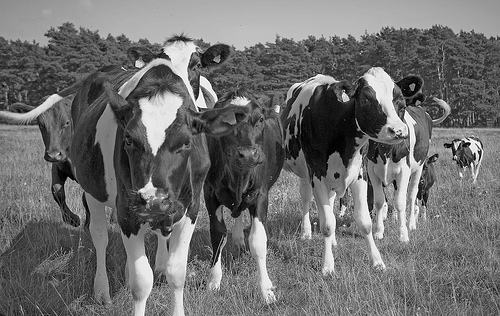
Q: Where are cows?
A: On grass.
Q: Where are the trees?
A: Behind cows.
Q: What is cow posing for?
A: Photo.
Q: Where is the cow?
A: In field.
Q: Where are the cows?
A: In field.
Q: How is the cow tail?
A: Up.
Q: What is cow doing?
A: Grazing.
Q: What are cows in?
A: Herd.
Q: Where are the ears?
A: Cow head.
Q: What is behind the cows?
A: Tall trees.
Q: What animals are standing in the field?
A: Cows.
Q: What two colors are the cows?
A: Black and white.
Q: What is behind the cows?
A: A row of trees.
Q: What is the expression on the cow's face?
A: Curiosity.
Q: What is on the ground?
A: Legs.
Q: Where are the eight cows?
A: In the field.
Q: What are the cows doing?
A: Grazing.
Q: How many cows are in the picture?
A: 8.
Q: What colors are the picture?
A: Black and white.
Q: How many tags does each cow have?
A: Two.